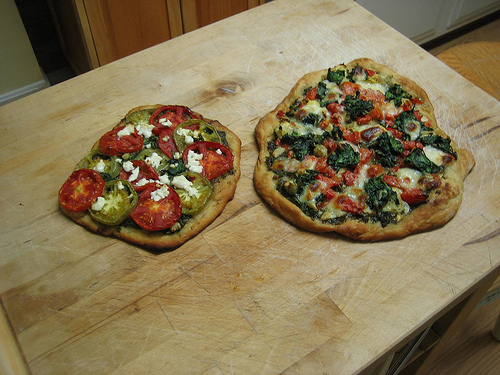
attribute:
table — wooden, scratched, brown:
[0, 0, 499, 374]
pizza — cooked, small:
[53, 101, 242, 254]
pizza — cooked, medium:
[251, 57, 478, 245]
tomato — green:
[175, 119, 223, 155]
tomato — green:
[172, 171, 213, 214]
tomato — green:
[88, 178, 138, 222]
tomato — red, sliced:
[184, 141, 234, 179]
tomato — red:
[129, 184, 181, 230]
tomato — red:
[59, 169, 106, 210]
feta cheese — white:
[185, 146, 205, 174]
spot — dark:
[197, 69, 248, 100]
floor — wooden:
[413, 20, 499, 374]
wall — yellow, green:
[0, 0, 47, 102]